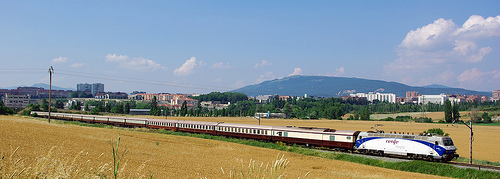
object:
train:
[30, 111, 459, 162]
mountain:
[226, 74, 493, 97]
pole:
[48, 71, 51, 123]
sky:
[290, 3, 366, 49]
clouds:
[408, 20, 469, 62]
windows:
[250, 129, 253, 134]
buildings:
[5, 92, 35, 111]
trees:
[304, 100, 350, 118]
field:
[71, 135, 115, 170]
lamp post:
[460, 120, 474, 164]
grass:
[35, 128, 74, 163]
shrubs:
[225, 104, 248, 117]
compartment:
[260, 129, 265, 135]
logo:
[385, 139, 399, 145]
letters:
[387, 139, 391, 143]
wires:
[52, 71, 270, 95]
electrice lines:
[56, 69, 306, 95]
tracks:
[453, 162, 500, 172]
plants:
[254, 141, 283, 148]